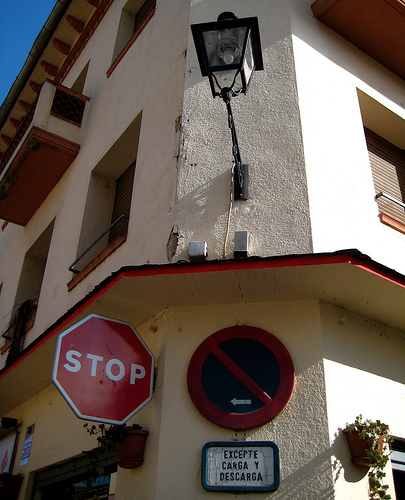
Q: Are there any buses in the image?
A: No, there are no buses.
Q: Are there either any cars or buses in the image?
A: No, there are no buses or cars.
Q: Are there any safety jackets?
A: No, there are no safety jackets.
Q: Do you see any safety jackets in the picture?
A: No, there are no safety jackets.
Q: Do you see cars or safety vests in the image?
A: No, there are no safety vests or cars.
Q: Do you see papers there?
A: No, there are no papers.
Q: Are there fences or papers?
A: No, there are no papers or fences.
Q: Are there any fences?
A: No, there are no fences.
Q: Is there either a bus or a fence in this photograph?
A: No, there are no fences or buses.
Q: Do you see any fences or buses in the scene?
A: No, there are no fences or buses.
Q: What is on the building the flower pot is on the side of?
A: The sign is on the building.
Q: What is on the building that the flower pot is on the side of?
A: The sign is on the building.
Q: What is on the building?
A: The sign is on the building.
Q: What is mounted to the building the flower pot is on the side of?
A: The sign is mounted to the building.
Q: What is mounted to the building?
A: The sign is mounted to the building.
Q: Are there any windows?
A: Yes, there is a window.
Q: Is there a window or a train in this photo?
A: Yes, there is a window.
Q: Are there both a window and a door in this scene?
A: No, there is a window but no doors.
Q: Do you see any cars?
A: No, there are no cars.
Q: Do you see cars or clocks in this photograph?
A: No, there are no cars or clocks.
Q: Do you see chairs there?
A: No, there are no chairs.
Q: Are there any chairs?
A: No, there are no chairs.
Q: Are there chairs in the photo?
A: No, there are no chairs.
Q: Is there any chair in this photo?
A: No, there are no chairs.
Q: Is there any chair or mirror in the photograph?
A: No, there are no chairs or mirrors.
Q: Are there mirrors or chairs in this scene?
A: No, there are no chairs or mirrors.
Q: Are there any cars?
A: No, there are no cars.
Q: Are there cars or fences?
A: No, there are no cars or fences.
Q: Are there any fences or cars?
A: No, there are no cars or fences.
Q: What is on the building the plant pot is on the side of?
A: The sign is on the building.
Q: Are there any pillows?
A: No, there are no pillows.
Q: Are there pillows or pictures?
A: No, there are no pillows or pictures.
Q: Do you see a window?
A: Yes, there is a window.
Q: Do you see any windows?
A: Yes, there is a window.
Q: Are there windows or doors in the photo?
A: Yes, there is a window.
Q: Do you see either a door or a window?
A: Yes, there is a window.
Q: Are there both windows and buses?
A: No, there is a window but no buses.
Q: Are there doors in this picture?
A: No, there are no doors.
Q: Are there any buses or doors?
A: No, there are no doors or buses.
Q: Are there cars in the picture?
A: No, there are no cars.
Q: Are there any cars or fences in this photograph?
A: No, there are no cars or fences.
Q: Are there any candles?
A: No, there are no candles.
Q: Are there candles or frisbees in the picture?
A: No, there are no candles or frisbees.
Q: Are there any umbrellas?
A: No, there are no umbrellas.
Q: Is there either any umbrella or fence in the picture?
A: No, there are no umbrellas or fences.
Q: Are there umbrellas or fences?
A: No, there are no umbrellas or fences.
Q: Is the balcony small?
A: Yes, the balcony is small.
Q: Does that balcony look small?
A: Yes, the balcony is small.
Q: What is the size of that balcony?
A: The balcony is small.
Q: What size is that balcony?
A: The balcony is small.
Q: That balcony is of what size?
A: The balcony is small.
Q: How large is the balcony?
A: The balcony is small.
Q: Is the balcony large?
A: No, the balcony is small.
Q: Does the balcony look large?
A: No, the balcony is small.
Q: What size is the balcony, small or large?
A: The balcony is small.